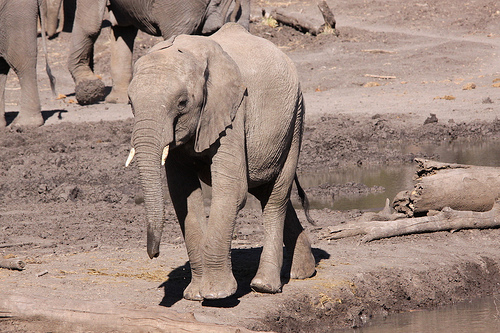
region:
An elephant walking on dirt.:
[123, 23, 316, 302]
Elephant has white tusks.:
[115, 141, 171, 167]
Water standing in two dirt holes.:
[130, 157, 498, 329]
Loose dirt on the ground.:
[0, 117, 493, 248]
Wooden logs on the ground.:
[319, 155, 497, 244]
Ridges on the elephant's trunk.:
[130, 115, 165, 258]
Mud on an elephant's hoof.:
[67, 75, 115, 107]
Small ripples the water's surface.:
[275, 161, 496, 331]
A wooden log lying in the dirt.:
[257, 0, 338, 31]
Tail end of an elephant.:
[0, 0, 57, 132]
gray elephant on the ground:
[95, 30, 321, 205]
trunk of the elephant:
[127, 125, 172, 260]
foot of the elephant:
[195, 260, 240, 310]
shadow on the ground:
[145, 270, 182, 317]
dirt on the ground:
[81, 257, 132, 312]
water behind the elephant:
[360, 165, 395, 201]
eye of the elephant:
[165, 85, 195, 115]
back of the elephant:
[231, 27, 271, 69]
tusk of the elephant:
[117, 141, 144, 171]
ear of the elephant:
[195, 46, 246, 133]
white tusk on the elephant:
[158, 146, 173, 174]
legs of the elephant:
[181, 249, 240, 311]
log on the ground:
[352, 146, 499, 241]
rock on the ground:
[272, 0, 352, 41]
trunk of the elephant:
[132, 168, 164, 264]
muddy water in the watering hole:
[382, 305, 479, 331]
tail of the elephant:
[287, 175, 325, 230]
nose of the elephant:
[72, 79, 107, 105]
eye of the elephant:
[173, 90, 191, 117]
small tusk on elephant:
[118, 145, 146, 166]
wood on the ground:
[404, 157, 499, 229]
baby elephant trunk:
[129, 114, 172, 273]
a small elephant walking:
[113, 29, 308, 329]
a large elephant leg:
[12, 8, 58, 138]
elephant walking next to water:
[0, 33, 440, 332]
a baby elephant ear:
[210, 48, 252, 191]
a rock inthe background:
[267, 5, 364, 47]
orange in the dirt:
[345, 58, 495, 110]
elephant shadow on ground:
[190, 209, 264, 331]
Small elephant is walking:
[127, 20, 319, 305]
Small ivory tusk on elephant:
[120, 143, 140, 168]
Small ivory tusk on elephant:
[160, 143, 170, 165]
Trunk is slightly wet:
[130, 92, 175, 259]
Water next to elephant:
[304, 281, 499, 331]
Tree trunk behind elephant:
[325, 208, 499, 248]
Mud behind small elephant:
[265, 123, 497, 214]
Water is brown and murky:
[329, 293, 499, 332]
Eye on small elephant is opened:
[175, 94, 189, 111]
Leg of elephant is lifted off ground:
[185, 135, 250, 299]